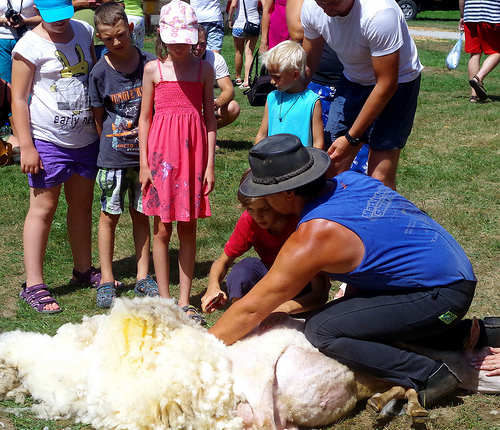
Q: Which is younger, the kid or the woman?
A: The kid is younger than the woman.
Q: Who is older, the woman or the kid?
A: The woman is older than the kid.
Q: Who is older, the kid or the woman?
A: The woman is older than the kid.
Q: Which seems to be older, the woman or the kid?
A: The woman is older than the kid.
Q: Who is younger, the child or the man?
A: The child is younger than the man.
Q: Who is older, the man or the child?
A: The man is older than the child.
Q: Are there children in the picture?
A: Yes, there is a child.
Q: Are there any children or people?
A: Yes, there is a child.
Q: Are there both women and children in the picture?
A: Yes, there are both a child and a woman.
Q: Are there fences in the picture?
A: No, there are no fences.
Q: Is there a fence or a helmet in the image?
A: No, there are no fences or helmets.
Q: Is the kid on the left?
A: Yes, the kid is on the left of the image.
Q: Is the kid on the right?
A: No, the kid is on the left of the image.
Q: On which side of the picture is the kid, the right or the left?
A: The kid is on the left of the image.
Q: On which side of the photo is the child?
A: The child is on the left of the image.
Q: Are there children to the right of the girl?
A: Yes, there is a child to the right of the girl.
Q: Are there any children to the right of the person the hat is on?
A: Yes, there is a child to the right of the girl.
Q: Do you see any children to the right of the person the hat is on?
A: Yes, there is a child to the right of the girl.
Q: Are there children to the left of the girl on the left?
A: No, the child is to the right of the girl.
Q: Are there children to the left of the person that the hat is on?
A: No, the child is to the right of the girl.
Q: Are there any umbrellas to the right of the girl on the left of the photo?
A: No, there is a child to the right of the girl.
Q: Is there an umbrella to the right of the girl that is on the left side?
A: No, there is a child to the right of the girl.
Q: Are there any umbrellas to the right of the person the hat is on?
A: No, there is a child to the right of the girl.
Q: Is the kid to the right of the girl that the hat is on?
A: Yes, the kid is to the right of the girl.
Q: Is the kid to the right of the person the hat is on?
A: Yes, the kid is to the right of the girl.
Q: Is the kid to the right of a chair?
A: No, the kid is to the right of the girl.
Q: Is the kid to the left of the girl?
A: No, the kid is to the right of the girl.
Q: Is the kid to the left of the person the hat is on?
A: No, the kid is to the right of the girl.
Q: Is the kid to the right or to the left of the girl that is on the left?
A: The kid is to the right of the girl.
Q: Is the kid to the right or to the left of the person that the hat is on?
A: The kid is to the right of the girl.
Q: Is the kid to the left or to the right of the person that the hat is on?
A: The kid is to the right of the girl.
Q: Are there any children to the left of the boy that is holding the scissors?
A: Yes, there is a child to the left of the boy.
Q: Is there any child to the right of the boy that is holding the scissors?
A: No, the child is to the left of the boy.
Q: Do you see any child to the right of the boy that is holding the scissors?
A: No, the child is to the left of the boy.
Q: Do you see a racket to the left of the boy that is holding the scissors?
A: No, there is a child to the left of the boy.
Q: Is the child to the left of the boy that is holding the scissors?
A: Yes, the child is to the left of the boy.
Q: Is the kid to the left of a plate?
A: No, the kid is to the left of the boy.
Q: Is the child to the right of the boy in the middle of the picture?
A: No, the child is to the left of the boy.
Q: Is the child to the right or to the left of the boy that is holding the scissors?
A: The child is to the left of the boy.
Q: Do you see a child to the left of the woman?
A: Yes, there is a child to the left of the woman.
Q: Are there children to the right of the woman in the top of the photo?
A: No, the child is to the left of the woman.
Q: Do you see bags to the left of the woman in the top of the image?
A: No, there is a child to the left of the woman.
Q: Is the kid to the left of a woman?
A: Yes, the kid is to the left of a woman.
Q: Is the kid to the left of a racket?
A: No, the kid is to the left of a woman.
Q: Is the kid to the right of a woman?
A: No, the kid is to the left of a woman.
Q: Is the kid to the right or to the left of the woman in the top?
A: The kid is to the left of the woman.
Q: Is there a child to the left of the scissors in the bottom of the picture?
A: Yes, there is a child to the left of the scissors.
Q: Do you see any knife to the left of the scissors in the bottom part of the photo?
A: No, there is a child to the left of the scissors.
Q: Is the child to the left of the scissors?
A: Yes, the child is to the left of the scissors.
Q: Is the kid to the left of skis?
A: No, the kid is to the left of the scissors.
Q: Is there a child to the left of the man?
A: Yes, there is a child to the left of the man.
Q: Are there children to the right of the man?
A: No, the child is to the left of the man.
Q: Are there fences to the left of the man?
A: No, there is a child to the left of the man.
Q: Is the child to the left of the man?
A: Yes, the child is to the left of the man.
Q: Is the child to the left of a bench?
A: No, the child is to the left of the man.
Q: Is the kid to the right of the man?
A: No, the kid is to the left of the man.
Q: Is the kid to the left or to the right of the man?
A: The kid is to the left of the man.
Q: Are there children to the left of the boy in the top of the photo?
A: Yes, there is a child to the left of the boy.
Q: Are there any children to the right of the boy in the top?
A: No, the child is to the left of the boy.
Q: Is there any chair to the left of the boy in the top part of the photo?
A: No, there is a child to the left of the boy.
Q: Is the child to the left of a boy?
A: Yes, the child is to the left of a boy.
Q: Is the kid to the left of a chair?
A: No, the kid is to the left of a boy.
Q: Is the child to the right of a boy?
A: No, the child is to the left of a boy.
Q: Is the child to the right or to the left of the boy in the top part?
A: The child is to the left of the boy.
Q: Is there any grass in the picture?
A: Yes, there is grass.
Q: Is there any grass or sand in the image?
A: Yes, there is grass.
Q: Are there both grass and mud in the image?
A: No, there is grass but no mud.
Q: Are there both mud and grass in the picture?
A: No, there is grass but no mud.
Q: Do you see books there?
A: No, there are no books.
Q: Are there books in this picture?
A: No, there are no books.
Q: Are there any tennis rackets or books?
A: No, there are no books or tennis rackets.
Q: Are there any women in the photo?
A: Yes, there is a woman.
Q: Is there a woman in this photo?
A: Yes, there is a woman.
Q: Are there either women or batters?
A: Yes, there is a woman.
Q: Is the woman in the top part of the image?
A: Yes, the woman is in the top of the image.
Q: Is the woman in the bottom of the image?
A: No, the woman is in the top of the image.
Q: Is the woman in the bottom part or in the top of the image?
A: The woman is in the top of the image.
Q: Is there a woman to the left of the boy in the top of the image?
A: Yes, there is a woman to the left of the boy.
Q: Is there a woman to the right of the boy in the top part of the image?
A: No, the woman is to the left of the boy.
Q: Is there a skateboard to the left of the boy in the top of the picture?
A: No, there is a woman to the left of the boy.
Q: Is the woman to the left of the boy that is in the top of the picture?
A: Yes, the woman is to the left of the boy.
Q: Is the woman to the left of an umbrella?
A: No, the woman is to the left of the boy.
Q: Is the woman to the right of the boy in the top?
A: No, the woman is to the left of the boy.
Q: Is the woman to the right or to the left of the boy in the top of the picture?
A: The woman is to the left of the boy.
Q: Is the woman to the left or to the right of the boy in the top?
A: The woman is to the left of the boy.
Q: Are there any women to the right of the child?
A: Yes, there is a woman to the right of the child.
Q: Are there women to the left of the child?
A: No, the woman is to the right of the child.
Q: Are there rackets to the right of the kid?
A: No, there is a woman to the right of the kid.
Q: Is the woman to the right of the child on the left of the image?
A: Yes, the woman is to the right of the kid.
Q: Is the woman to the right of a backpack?
A: No, the woman is to the right of the kid.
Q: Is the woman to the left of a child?
A: No, the woman is to the right of a child.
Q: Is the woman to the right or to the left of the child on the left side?
A: The woman is to the right of the kid.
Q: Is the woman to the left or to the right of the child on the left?
A: The woman is to the right of the kid.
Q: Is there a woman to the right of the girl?
A: Yes, there is a woman to the right of the girl.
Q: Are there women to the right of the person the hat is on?
A: Yes, there is a woman to the right of the girl.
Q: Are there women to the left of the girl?
A: No, the woman is to the right of the girl.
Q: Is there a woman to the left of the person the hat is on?
A: No, the woman is to the right of the girl.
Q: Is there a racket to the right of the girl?
A: No, there is a woman to the right of the girl.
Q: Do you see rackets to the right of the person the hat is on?
A: No, there is a woman to the right of the girl.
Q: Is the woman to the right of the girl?
A: Yes, the woman is to the right of the girl.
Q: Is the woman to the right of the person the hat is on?
A: Yes, the woman is to the right of the girl.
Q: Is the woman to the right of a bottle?
A: No, the woman is to the right of the girl.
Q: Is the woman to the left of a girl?
A: No, the woman is to the right of a girl.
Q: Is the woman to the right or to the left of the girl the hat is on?
A: The woman is to the right of the girl.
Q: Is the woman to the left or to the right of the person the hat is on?
A: The woman is to the right of the girl.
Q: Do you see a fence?
A: No, there are no fences.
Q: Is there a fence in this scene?
A: No, there are no fences.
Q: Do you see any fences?
A: No, there are no fences.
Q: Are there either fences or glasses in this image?
A: No, there are no fences or glasses.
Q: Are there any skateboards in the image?
A: No, there are no skateboards.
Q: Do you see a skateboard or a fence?
A: No, there are no skateboards or fences.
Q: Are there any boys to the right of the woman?
A: Yes, there is a boy to the right of the woman.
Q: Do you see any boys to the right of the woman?
A: Yes, there is a boy to the right of the woman.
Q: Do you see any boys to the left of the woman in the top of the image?
A: No, the boy is to the right of the woman.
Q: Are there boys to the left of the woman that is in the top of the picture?
A: No, the boy is to the right of the woman.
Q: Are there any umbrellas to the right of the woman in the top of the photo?
A: No, there is a boy to the right of the woman.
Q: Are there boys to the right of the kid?
A: Yes, there is a boy to the right of the kid.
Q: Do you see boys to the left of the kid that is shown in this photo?
A: No, the boy is to the right of the kid.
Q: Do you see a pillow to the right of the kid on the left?
A: No, there is a boy to the right of the child.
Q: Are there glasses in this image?
A: No, there are no glasses.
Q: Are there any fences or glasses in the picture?
A: No, there are no glasses or fences.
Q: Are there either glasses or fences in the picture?
A: No, there are no glasses or fences.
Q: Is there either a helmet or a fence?
A: No, there are no fences or helmets.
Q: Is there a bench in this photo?
A: No, there are no benches.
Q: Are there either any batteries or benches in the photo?
A: No, there are no benches or batteries.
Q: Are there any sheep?
A: Yes, there is a sheep.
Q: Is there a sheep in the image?
A: Yes, there is a sheep.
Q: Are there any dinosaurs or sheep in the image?
A: Yes, there is a sheep.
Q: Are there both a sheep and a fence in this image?
A: No, there is a sheep but no fences.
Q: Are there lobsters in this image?
A: No, there are no lobsters.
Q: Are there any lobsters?
A: No, there are no lobsters.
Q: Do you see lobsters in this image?
A: No, there are no lobsters.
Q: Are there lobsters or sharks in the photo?
A: No, there are no lobsters or sharks.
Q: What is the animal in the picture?
A: The animal is a sheep.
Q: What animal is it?
A: The animal is a sheep.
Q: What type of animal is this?
A: This is a sheep.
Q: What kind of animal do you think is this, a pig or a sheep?
A: This is a sheep.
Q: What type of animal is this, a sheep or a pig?
A: This is a sheep.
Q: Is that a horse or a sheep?
A: That is a sheep.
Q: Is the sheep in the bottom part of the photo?
A: Yes, the sheep is in the bottom of the image.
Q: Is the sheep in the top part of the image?
A: No, the sheep is in the bottom of the image.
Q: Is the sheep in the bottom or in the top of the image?
A: The sheep is in the bottom of the image.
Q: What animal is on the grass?
A: The sheep is on the grass.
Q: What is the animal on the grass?
A: The animal is a sheep.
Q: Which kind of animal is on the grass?
A: The animal is a sheep.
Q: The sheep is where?
A: The sheep is on the grass.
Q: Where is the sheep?
A: The sheep is on the grass.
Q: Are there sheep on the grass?
A: Yes, there is a sheep on the grass.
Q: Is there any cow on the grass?
A: No, there is a sheep on the grass.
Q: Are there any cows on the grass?
A: No, there is a sheep on the grass.